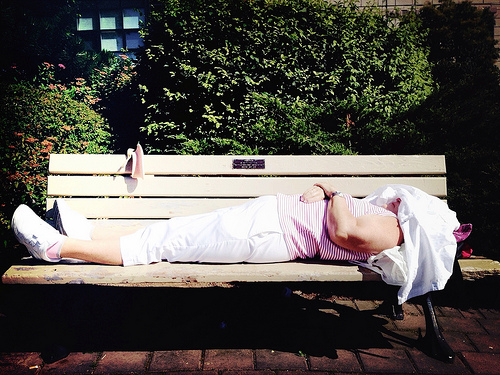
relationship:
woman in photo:
[8, 181, 476, 266] [7, 58, 487, 374]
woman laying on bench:
[19, 189, 477, 298] [57, 150, 460, 285]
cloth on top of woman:
[360, 181, 462, 307] [19, 189, 477, 298]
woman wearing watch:
[19, 189, 477, 298] [325, 188, 342, 200]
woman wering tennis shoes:
[19, 189, 477, 298] [13, 198, 87, 269]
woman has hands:
[19, 189, 477, 298] [300, 183, 352, 212]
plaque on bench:
[224, 155, 271, 173] [57, 150, 460, 285]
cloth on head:
[396, 185, 456, 268] [388, 195, 457, 242]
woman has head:
[19, 189, 477, 298] [388, 195, 457, 242]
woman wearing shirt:
[19, 189, 477, 298] [278, 202, 388, 256]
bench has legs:
[57, 150, 460, 285] [402, 301, 455, 374]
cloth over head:
[360, 181, 462, 307] [388, 195, 457, 242]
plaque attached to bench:
[224, 155, 271, 173] [57, 150, 460, 285]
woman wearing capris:
[19, 189, 477, 298] [124, 217, 290, 265]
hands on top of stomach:
[300, 183, 352, 212] [265, 192, 339, 237]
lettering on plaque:
[239, 161, 258, 167] [224, 155, 271, 173]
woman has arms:
[19, 189, 477, 298] [318, 182, 371, 254]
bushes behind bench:
[15, 70, 430, 153] [57, 150, 460, 285]